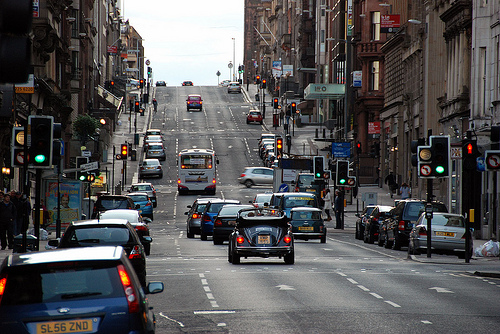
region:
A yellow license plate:
[39, 312, 94, 333]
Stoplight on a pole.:
[413, 136, 452, 182]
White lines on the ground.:
[355, 281, 397, 305]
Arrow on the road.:
[420, 280, 458, 300]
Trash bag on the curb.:
[473, 228, 499, 262]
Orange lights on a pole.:
[115, 141, 129, 175]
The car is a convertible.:
[232, 209, 300, 257]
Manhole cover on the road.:
[188, 301, 247, 327]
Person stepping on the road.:
[320, 184, 339, 222]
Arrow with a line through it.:
[475, 150, 499, 174]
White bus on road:
[169, 137, 223, 200]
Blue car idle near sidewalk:
[0, 240, 159, 329]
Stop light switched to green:
[415, 117, 455, 256]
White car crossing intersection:
[227, 155, 283, 192]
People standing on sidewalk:
[2, 182, 37, 256]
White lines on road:
[325, 248, 412, 332]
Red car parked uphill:
[237, 102, 268, 131]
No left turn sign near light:
[410, 160, 435, 182]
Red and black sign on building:
[365, 8, 415, 45]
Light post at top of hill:
[224, 27, 244, 86]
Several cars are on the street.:
[0, 68, 470, 332]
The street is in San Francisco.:
[108, 47, 498, 332]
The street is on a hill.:
[121, 68, 288, 240]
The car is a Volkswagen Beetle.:
[215, 202, 302, 269]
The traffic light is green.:
[402, 130, 462, 187]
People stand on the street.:
[310, 177, 358, 233]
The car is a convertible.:
[207, 195, 309, 273]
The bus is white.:
[164, 137, 229, 200]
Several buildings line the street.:
[239, 2, 497, 189]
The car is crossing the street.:
[227, 157, 306, 198]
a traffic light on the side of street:
[423, 125, 456, 211]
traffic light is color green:
[423, 128, 453, 179]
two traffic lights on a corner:
[304, 149, 354, 191]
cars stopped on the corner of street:
[172, 185, 343, 278]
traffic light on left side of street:
[23, 108, 60, 235]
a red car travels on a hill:
[176, 86, 211, 116]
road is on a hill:
[146, 76, 269, 203]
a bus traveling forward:
[170, 139, 221, 196]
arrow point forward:
[265, 271, 301, 301]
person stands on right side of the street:
[312, 181, 337, 225]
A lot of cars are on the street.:
[111, 72, 338, 267]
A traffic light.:
[429, 127, 453, 186]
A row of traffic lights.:
[306, 132, 459, 193]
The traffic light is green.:
[428, 133, 456, 182]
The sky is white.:
[158, 5, 217, 57]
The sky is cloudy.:
[161, 3, 220, 58]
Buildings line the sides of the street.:
[243, 5, 498, 257]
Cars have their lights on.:
[180, 177, 304, 258]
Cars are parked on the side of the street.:
[351, 190, 481, 262]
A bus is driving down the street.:
[171, 137, 222, 200]